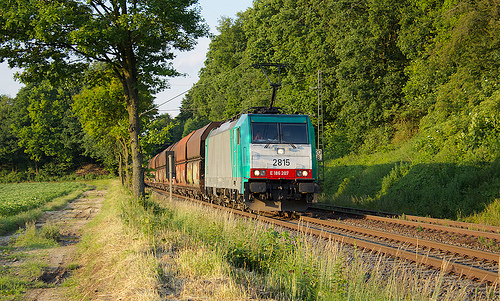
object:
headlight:
[300, 168, 309, 178]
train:
[144, 107, 317, 214]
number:
[271, 156, 278, 169]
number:
[275, 157, 284, 168]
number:
[281, 157, 288, 166]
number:
[284, 157, 292, 167]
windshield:
[250, 121, 310, 146]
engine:
[232, 111, 320, 211]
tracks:
[153, 183, 499, 285]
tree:
[0, 0, 206, 214]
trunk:
[126, 93, 150, 213]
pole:
[168, 153, 176, 205]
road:
[0, 181, 108, 300]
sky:
[3, 2, 255, 117]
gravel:
[254, 219, 497, 298]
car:
[184, 120, 221, 197]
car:
[172, 129, 194, 194]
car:
[157, 142, 170, 192]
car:
[151, 152, 160, 189]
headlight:
[254, 168, 260, 177]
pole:
[314, 64, 327, 196]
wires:
[139, 62, 317, 113]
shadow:
[316, 155, 500, 223]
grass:
[313, 126, 498, 228]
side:
[143, 114, 247, 201]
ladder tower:
[316, 61, 327, 198]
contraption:
[251, 55, 298, 114]